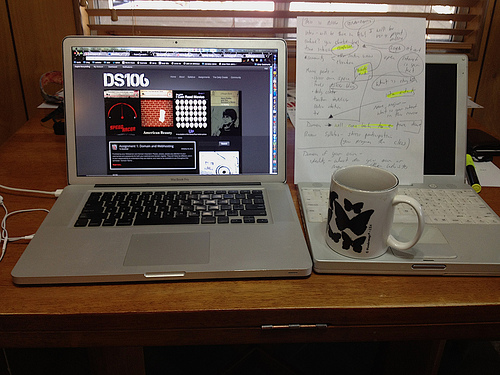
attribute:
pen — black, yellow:
[462, 153, 482, 191]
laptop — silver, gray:
[5, 30, 317, 292]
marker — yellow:
[463, 149, 484, 194]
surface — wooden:
[114, 279, 464, 360]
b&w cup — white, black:
[322, 162, 424, 258]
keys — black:
[72, 185, 273, 229]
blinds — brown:
[75, 2, 487, 69]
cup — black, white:
[322, 164, 424, 256]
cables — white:
[0, 180, 60, 248]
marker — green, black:
[463, 152, 484, 197]